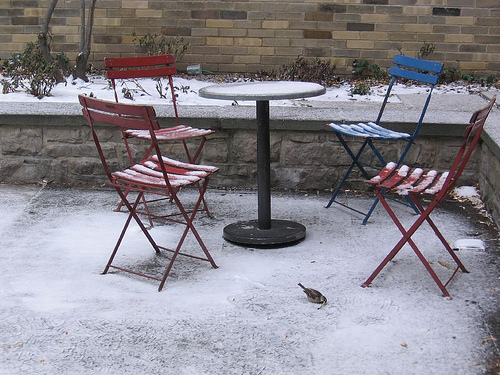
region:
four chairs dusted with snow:
[68, 30, 489, 307]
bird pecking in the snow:
[295, 280, 330, 312]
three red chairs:
[73, 50, 482, 297]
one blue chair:
[320, 53, 450, 223]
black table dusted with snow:
[199, 75, 324, 251]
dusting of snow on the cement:
[3, 184, 493, 374]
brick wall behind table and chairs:
[5, 4, 497, 71]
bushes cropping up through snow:
[6, 48, 482, 103]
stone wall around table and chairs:
[3, 95, 499, 213]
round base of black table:
[225, 218, 300, 248]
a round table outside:
[210, 57, 327, 270]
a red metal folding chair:
[360, 94, 492, 316]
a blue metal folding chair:
[315, 54, 441, 221]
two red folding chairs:
[90, 43, 207, 308]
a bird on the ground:
[300, 280, 327, 320]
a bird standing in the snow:
[294, 271, 354, 323]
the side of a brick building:
[170, 9, 389, 57]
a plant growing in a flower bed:
[10, 57, 82, 100]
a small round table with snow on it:
[204, 56, 325, 267]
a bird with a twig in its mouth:
[288, 282, 342, 320]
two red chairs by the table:
[87, 46, 220, 269]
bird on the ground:
[276, 274, 357, 314]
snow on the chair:
[373, 164, 445, 200]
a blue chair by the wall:
[334, 59, 435, 166]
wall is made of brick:
[2, 126, 75, 183]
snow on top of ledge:
[20, 87, 191, 108]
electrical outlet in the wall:
[185, 55, 210, 82]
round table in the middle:
[207, 67, 323, 253]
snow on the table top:
[192, 78, 332, 95]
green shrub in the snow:
[2, 47, 92, 86]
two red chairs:
[54, 39, 245, 296]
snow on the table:
[200, 75, 317, 99]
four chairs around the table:
[69, 33, 496, 309]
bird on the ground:
[291, 281, 333, 309]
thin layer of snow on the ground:
[2, 178, 499, 372]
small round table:
[196, 64, 342, 259]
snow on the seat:
[329, 115, 408, 145]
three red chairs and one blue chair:
[79, 40, 499, 313]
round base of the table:
[217, 204, 314, 255]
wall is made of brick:
[4, 3, 499, 89]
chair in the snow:
[72, 96, 219, 301]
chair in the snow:
[380, 108, 480, 324]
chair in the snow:
[335, 35, 412, 225]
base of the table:
[227, 216, 308, 261]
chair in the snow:
[111, 53, 217, 178]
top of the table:
[199, 63, 322, 114]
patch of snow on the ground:
[269, 323, 300, 353]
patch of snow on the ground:
[385, 325, 402, 347]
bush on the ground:
[28, 70, 48, 95]